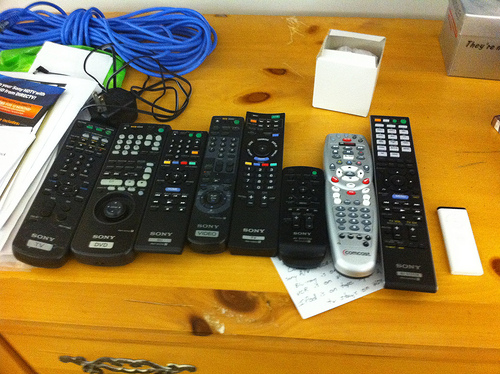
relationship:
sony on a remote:
[84, 232, 114, 253] [75, 119, 176, 275]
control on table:
[12, 111, 437, 293] [2, 8, 499, 372]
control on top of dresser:
[12, 111, 437, 293] [3, 10, 498, 372]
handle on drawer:
[52, 350, 201, 372] [2, 342, 498, 372]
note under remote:
[303, 275, 343, 308] [311, 136, 382, 290]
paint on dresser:
[205, 305, 248, 335] [3, 10, 498, 372]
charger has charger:
[81, 41, 193, 128] [81, 41, 193, 128]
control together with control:
[12, 111, 437, 293] [12, 111, 437, 293]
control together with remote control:
[12, 111, 437, 293] [281, 167, 326, 255]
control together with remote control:
[12, 111, 437, 293] [199, 127, 231, 249]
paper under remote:
[270, 245, 383, 320] [279, 156, 324, 265]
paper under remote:
[270, 245, 383, 320] [321, 122, 381, 283]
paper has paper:
[270, 242, 382, 317] [270, 245, 383, 320]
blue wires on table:
[0, 1, 217, 78] [2, 8, 499, 372]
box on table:
[309, 25, 390, 123] [2, 8, 499, 372]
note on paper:
[285, 260, 382, 308] [265, 234, 392, 328]